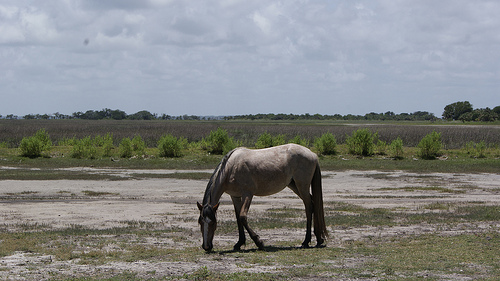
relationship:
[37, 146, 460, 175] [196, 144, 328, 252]
grass behind horse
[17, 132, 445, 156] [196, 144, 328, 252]
bushes behind horse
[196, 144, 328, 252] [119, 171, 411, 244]
horse on dirt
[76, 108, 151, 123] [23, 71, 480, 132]
trees in background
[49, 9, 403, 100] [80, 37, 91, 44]
sky has spec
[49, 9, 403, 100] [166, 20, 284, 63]
sky has clouds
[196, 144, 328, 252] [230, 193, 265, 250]
horse has legs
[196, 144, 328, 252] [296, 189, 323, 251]
horse has legs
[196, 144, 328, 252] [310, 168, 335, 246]
horse has tail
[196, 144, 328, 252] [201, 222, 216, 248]
horse has nose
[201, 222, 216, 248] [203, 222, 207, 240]
nose has markings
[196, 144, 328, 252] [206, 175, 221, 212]
horse has neck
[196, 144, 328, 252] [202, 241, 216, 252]
horse has mouth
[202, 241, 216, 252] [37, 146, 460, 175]
mouth close to grass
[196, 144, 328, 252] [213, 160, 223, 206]
horse has mane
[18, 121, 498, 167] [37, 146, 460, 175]
field has grass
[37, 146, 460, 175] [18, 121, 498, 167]
grass on field